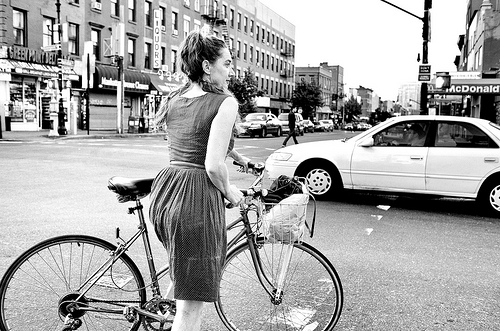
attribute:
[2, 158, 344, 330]
bicycle — black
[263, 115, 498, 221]
car — white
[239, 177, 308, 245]
basket — metal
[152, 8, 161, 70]
sign — white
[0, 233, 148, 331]
wheel — rear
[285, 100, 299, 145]
man — walking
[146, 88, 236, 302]
dress — sleeveless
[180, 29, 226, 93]
hair — long, dark